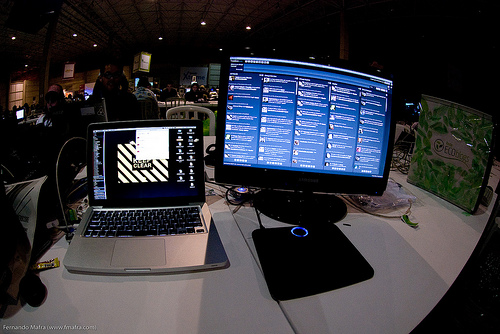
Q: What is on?
A: The laptop.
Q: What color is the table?
A: White.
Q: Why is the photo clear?
A: The area is lit.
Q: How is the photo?
A: Clear.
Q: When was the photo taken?
A: Nighttime.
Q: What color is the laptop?
A: Grey.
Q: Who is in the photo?
A: Nobody.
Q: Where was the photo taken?
A: At a cafe.